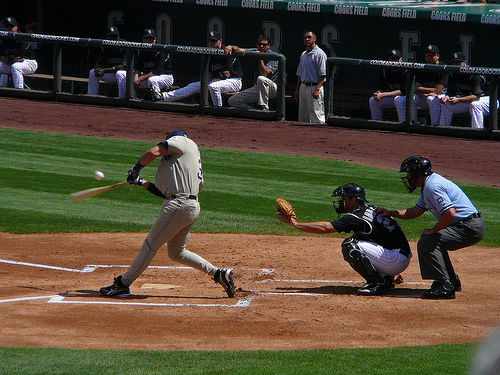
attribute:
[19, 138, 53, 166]
grass — green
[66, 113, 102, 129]
dirt — red, brown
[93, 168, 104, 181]
ball — air, white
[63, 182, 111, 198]
baseball bat — swung, brown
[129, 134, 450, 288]
people — sitting, playing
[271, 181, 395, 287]
catcher — waiting, ready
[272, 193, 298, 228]
mitt — brown, reaching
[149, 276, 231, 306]
home plate — dirty, here, dirt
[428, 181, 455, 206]
shirt — blue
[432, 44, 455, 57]
helmets — black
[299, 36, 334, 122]
man — hitting, standing, watching, swinging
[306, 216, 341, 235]
arm — extended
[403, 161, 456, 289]
umpire — standing, waiting, watching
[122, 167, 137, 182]
glove — baseball, for baseball, up, brown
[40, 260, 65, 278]
lines — marking, white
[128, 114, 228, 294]
batter — ready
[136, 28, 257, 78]
players — watching, sidelined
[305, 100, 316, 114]
pants — white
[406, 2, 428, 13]
banner — green